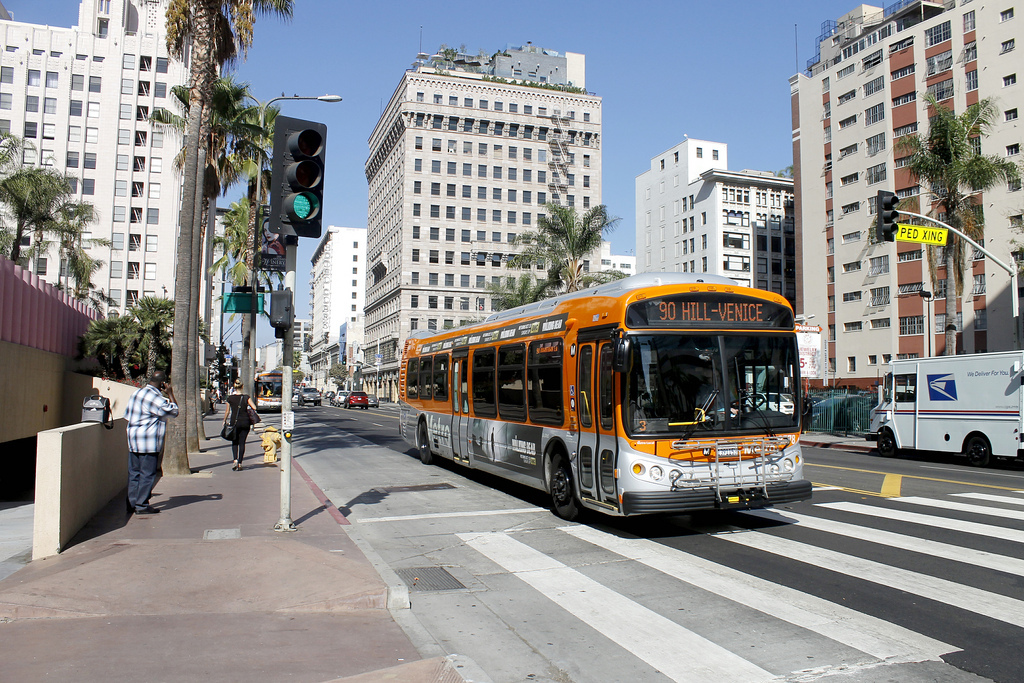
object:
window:
[581, 131, 594, 147]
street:
[250, 377, 1020, 682]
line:
[452, 532, 791, 682]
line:
[452, 487, 1022, 683]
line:
[704, 525, 1022, 616]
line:
[811, 495, 1024, 544]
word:
[682, 302, 712, 321]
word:
[718, 303, 764, 321]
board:
[621, 283, 793, 329]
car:
[343, 391, 370, 409]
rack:
[572, 411, 706, 518]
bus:
[397, 273, 811, 522]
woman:
[221, 378, 262, 472]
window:
[583, 154, 589, 168]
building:
[362, 27, 603, 401]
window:
[395, 230, 400, 247]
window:
[110, 233, 123, 251]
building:
[0, 0, 217, 380]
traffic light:
[269, 113, 327, 237]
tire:
[548, 454, 580, 522]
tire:
[419, 419, 432, 465]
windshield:
[621, 331, 804, 440]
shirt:
[124, 384, 178, 454]